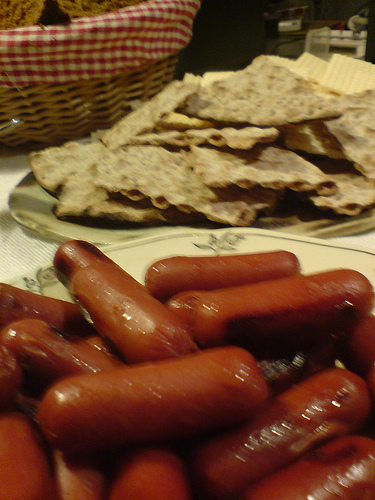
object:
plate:
[110, 190, 345, 276]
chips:
[36, 51, 375, 239]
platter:
[8, 170, 375, 244]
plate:
[0, 133, 373, 233]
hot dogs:
[0, 240, 375, 500]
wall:
[104, 90, 200, 133]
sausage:
[37, 347, 272, 449]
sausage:
[53, 240, 196, 362]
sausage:
[144, 249, 301, 298]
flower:
[192, 229, 247, 252]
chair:
[304, 29, 367, 59]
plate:
[24, 118, 362, 361]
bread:
[2, 3, 125, 29]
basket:
[0, 55, 178, 146]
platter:
[0, 228, 375, 319]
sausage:
[108, 449, 191, 498]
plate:
[11, 135, 373, 250]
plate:
[7, 229, 372, 499]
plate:
[11, 119, 373, 245]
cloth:
[0, 0, 200, 88]